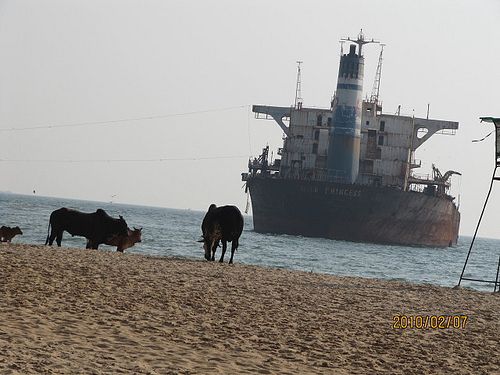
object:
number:
[461, 316, 469, 328]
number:
[393, 315, 401, 328]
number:
[431, 316, 438, 329]